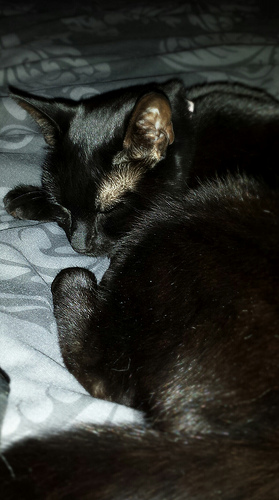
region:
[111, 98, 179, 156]
The cats right ear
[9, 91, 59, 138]
The cats left ear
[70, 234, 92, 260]
The cats nose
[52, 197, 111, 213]
The cats closed eyes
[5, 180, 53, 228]
The paw the cat is sleeping on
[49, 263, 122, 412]
The back foot of the cat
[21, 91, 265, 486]
A cat that is sleeping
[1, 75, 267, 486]
The bed spread the cat is sleeping on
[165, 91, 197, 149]
The collar of the cat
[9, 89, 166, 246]
The head of the cat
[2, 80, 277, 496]
a resting black cat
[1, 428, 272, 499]
a black cat's tail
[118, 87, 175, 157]
a cat's left ear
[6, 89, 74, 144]
a cat's right ear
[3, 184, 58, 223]
a cat's front paw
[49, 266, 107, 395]
a cat's rear paw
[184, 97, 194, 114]
a white cat collar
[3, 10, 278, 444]
a grey print blanket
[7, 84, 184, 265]
a black cat's head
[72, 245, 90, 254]
a cat's black nose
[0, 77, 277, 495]
Black cat is laying on bed.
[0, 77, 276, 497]
Black cat is sleeping on bed.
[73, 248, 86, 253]
Cat has black nose.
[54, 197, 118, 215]
Cats eyes are shut.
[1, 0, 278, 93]
Comforter is bed is gray.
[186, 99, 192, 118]
Cat has on white collar.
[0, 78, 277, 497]
Black cat is sleeping.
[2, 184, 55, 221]
Cat has paw next to chin.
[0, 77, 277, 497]
Black cat napping on the bed.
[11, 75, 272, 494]
cat sleeping on bed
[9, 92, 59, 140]
ear of the phone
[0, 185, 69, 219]
paw of the cat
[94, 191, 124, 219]
eye of the cat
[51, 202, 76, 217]
eye of the cat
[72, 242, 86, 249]
nose of the cat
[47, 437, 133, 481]
tail of the cat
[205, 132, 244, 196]
fur of the cat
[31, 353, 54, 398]
sheet on the bed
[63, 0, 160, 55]
the sheets are dark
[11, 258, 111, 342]
cat on the sheets